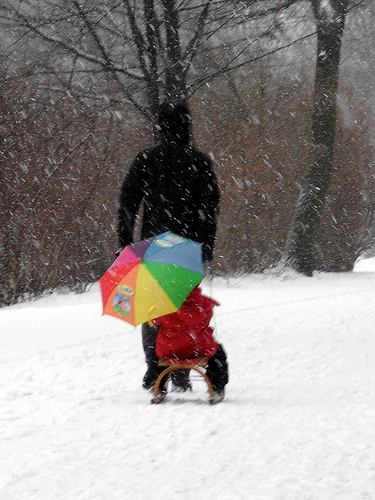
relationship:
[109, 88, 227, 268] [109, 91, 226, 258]
he wears jacket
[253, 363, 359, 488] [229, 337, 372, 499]
snow on place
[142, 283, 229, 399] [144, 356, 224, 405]
child on sled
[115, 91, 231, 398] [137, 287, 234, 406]
he pulls child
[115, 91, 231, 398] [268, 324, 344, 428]
he in snow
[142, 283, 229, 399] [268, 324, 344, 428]
child in snow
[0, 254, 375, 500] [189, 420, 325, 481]
snow on ground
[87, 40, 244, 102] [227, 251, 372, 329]
trees on area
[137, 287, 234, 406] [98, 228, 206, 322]
child holding umbrella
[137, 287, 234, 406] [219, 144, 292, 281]
child in snowfall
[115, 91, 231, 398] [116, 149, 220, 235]
he in jacket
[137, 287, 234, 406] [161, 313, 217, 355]
child in jacket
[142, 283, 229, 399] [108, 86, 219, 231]
child with parent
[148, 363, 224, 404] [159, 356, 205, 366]
sled a bench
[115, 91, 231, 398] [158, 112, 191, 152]
he wearing mask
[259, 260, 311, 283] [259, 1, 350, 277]
pile on trunk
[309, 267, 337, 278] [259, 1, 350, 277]
pile on trunk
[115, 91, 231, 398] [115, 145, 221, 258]
he in jacket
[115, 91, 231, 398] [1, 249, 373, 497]
he walking in snow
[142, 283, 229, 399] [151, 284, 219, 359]
child in jacket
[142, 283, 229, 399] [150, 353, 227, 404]
child on seigh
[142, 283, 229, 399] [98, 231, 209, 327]
child with umbrella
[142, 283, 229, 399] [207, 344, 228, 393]
child wearing pants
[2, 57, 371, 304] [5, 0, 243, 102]
bushes near trees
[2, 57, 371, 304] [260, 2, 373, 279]
bushes near tree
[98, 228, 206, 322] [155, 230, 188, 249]
umbrella has advertisement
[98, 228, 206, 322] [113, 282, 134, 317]
umbrella has advertisement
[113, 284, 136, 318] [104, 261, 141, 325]
advertisement on section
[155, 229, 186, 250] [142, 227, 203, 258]
advertisement on section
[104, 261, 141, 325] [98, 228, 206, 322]
section of umbrella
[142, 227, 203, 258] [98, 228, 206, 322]
section of umbrella